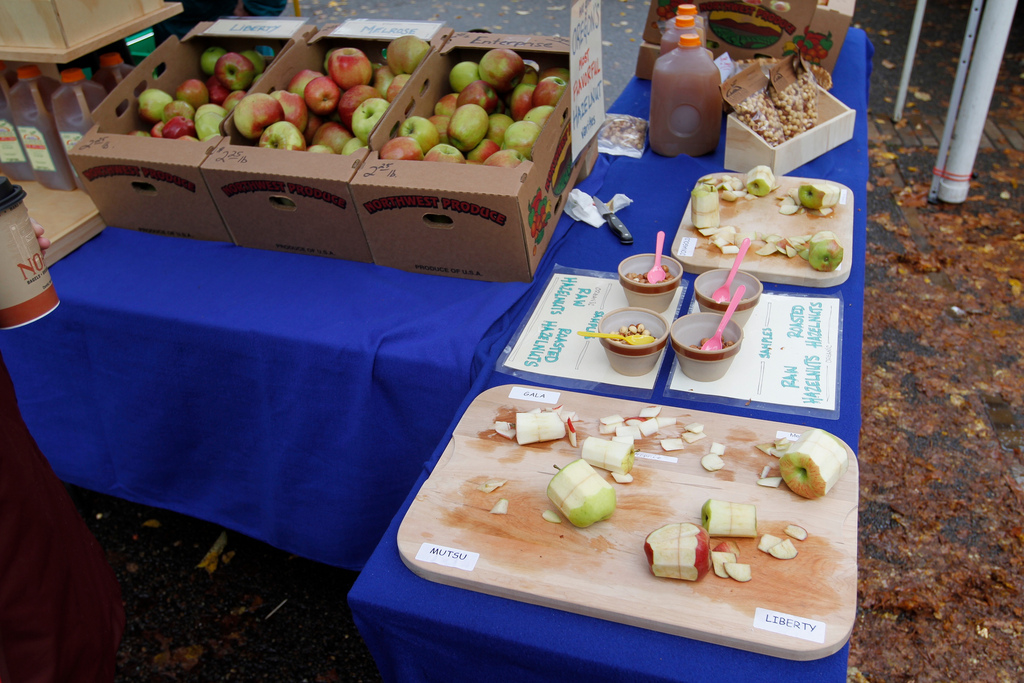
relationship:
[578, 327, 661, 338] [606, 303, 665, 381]
spoon in the bowl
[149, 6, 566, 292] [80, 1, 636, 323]
apples in box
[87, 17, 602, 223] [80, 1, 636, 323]
apples in box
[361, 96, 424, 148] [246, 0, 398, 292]
apple in box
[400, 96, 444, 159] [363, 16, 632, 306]
apple in box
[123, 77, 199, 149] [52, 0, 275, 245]
apple in box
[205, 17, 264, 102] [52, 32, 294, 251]
apple in box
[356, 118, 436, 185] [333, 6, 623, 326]
apple in box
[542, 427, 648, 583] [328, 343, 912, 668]
apple on table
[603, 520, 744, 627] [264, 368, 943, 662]
apple on table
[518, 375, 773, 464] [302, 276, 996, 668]
apples on table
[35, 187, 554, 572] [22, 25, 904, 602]
cloth covering table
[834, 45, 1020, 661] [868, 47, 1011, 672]
leaves covering ground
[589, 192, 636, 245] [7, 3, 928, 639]
knife on table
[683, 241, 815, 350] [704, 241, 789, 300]
spoon in bowl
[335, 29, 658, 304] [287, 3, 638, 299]
box has apples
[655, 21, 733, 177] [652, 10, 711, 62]
jug has a lid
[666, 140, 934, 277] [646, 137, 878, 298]
apples on cutting board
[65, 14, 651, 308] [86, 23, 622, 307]
boxes of apples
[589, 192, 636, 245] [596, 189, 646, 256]
knife has a handle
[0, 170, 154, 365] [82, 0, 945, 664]
cup on table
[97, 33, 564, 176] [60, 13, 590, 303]
apples in boxes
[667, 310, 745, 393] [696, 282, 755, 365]
bowl with spoon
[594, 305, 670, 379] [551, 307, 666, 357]
bowl with spoon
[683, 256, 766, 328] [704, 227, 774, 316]
bowl with spoon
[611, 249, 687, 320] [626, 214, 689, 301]
bowl with spoon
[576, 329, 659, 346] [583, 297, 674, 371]
spoon in bowl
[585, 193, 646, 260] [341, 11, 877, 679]
knife on table